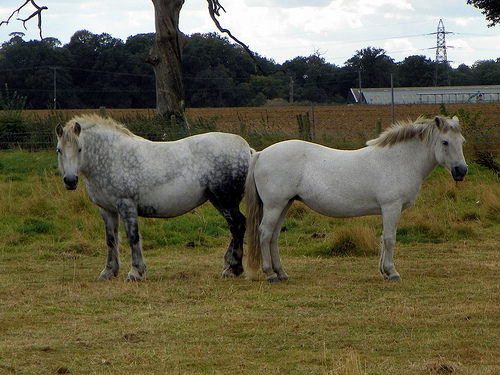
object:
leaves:
[0, 32, 500, 109]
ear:
[74, 122, 81, 135]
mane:
[374, 114, 460, 147]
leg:
[119, 206, 144, 278]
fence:
[0, 112, 500, 155]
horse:
[247, 116, 469, 283]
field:
[0, 183, 499, 375]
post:
[312, 104, 316, 141]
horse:
[54, 112, 252, 282]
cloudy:
[215, 0, 499, 64]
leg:
[257, 197, 289, 276]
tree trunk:
[145, 0, 189, 117]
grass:
[0, 208, 499, 374]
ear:
[55, 123, 63, 136]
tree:
[0, 27, 499, 108]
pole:
[428, 18, 455, 86]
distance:
[0, 0, 499, 126]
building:
[350, 85, 500, 105]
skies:
[0, 0, 500, 61]